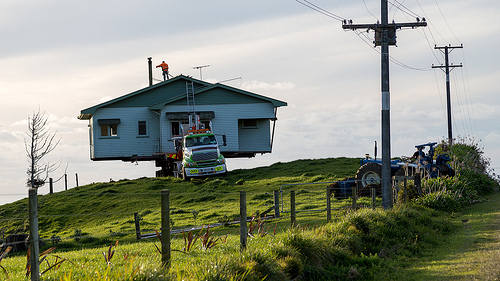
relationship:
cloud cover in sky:
[294, 26, 328, 66] [264, 32, 361, 94]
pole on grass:
[348, 5, 413, 218] [350, 167, 474, 262]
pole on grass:
[433, 38, 466, 145] [350, 167, 474, 262]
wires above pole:
[396, 5, 451, 19] [343, 1, 425, 210]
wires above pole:
[396, 5, 451, 19] [434, 42, 461, 145]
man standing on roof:
[156, 61, 169, 81] [77, 70, 293, 127]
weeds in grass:
[290, 225, 389, 264] [134, 167, 306, 270]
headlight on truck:
[187, 157, 194, 164] [174, 127, 226, 180]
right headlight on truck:
[215, 157, 223, 166] [157, 127, 230, 179]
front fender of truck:
[182, 167, 241, 181] [147, 135, 259, 173]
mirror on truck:
[208, 122, 233, 153] [158, 119, 245, 180]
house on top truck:
[76, 57, 287, 162] [168, 123, 230, 183]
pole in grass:
[19, 187, 49, 276] [222, 222, 344, 264]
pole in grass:
[152, 182, 184, 262] [222, 222, 344, 264]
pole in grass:
[229, 183, 254, 248] [222, 222, 344, 264]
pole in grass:
[280, 183, 301, 225] [222, 222, 344, 264]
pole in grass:
[322, 180, 337, 230] [222, 222, 344, 264]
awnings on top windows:
[96, 105, 218, 126] [90, 122, 120, 141]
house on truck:
[61, 57, 302, 176] [159, 123, 230, 193]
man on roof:
[156, 61, 169, 81] [69, 81, 318, 113]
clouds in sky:
[308, 86, 378, 131] [1, 3, 497, 122]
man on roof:
[153, 60, 171, 78] [75, 74, 201, 114]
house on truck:
[76, 57, 287, 162] [155, 129, 228, 180]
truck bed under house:
[150, 151, 188, 177] [75, 75, 288, 158]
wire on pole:
[296, 0, 470, 90] [343, 1, 425, 210]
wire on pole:
[296, 0, 470, 90] [238, 189, 247, 249]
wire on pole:
[296, 0, 470, 90] [430, 43, 463, 146]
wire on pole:
[296, 0, 470, 90] [25, 189, 37, 279]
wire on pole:
[296, 0, 470, 90] [159, 189, 171, 268]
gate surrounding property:
[3, 170, 462, 279] [2, 155, 483, 275]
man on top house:
[156, 61, 169, 81] [73, 70, 284, 166]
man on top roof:
[156, 61, 169, 81] [73, 74, 288, 110]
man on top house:
[156, 61, 169, 81] [75, 56, 289, 157]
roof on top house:
[73, 74, 288, 110] [75, 56, 289, 157]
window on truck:
[176, 138, 224, 150] [156, 105, 254, 200]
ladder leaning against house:
[181, 74, 204, 132] [53, 47, 331, 208]